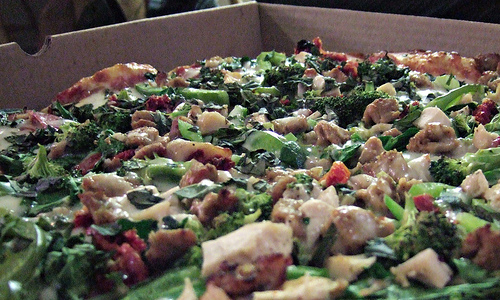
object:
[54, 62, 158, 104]
crust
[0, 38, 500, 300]
florets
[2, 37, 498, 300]
chicken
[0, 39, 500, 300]
broccoli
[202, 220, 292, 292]
hunk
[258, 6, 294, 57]
shadow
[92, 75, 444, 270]
kale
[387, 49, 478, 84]
curled edge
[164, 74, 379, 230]
surface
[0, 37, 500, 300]
meat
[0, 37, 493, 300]
dish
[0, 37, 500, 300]
topping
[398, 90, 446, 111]
cheese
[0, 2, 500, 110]
box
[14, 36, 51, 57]
cutout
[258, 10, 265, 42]
corner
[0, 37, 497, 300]
food